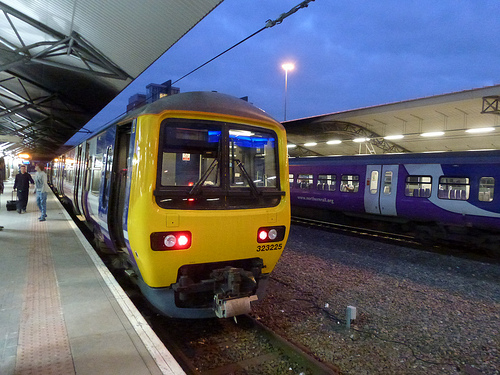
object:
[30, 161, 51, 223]
person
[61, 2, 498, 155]
sky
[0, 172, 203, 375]
platform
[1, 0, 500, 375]
train station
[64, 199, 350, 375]
railway line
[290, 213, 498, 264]
railway line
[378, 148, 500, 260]
cars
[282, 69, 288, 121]
pole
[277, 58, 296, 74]
light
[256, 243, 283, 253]
32325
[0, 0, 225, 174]
roof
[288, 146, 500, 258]
train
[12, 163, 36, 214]
person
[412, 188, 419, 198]
seat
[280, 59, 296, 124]
light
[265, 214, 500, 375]
gravel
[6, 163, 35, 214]
pulling luggage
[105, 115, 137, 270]
door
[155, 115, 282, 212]
window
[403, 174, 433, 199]
window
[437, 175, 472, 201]
window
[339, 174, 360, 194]
window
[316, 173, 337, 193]
window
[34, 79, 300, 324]
train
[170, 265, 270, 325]
metal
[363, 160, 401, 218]
door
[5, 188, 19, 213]
luggage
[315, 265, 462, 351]
rocks